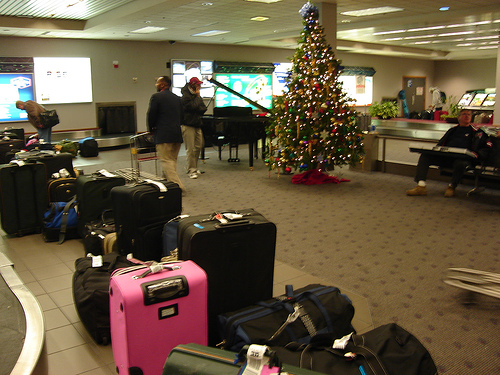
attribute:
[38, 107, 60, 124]
bag — black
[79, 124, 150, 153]
conveyor belt — silver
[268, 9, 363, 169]
tree — Christmas, lit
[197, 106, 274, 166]
piano — black, grand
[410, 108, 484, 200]
man — sitting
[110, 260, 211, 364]
suitcase — pink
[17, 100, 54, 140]
man — bent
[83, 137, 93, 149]
hat — red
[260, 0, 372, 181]
tree — large